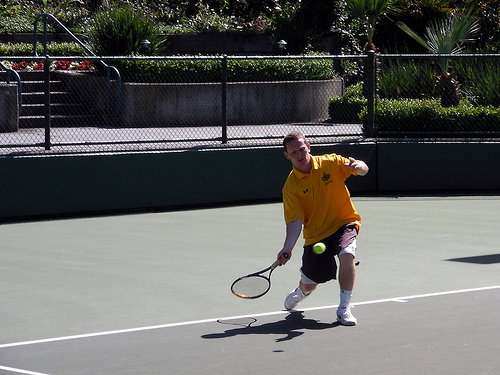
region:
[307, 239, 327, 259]
tennis ball in the air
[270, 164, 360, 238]
man wearing a yellow shirt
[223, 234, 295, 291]
man holding a tennis racket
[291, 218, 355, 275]
man wearing brown shorts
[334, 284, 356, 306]
man wearing white socks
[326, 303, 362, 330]
man wearing white shoes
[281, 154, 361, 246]
man has on a yellow shirt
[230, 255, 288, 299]
man is holding a black racket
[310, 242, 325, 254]
green tennis ball is in the air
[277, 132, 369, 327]
man is on a tennis court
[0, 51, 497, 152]
fence is black and metal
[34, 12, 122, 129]
railing is black and metal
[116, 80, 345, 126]
wall is concrete and gray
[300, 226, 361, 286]
mans shorts are black and white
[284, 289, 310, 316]
mans shoe is black and white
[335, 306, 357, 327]
mans shoe is black and white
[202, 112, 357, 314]
the man is playing tennis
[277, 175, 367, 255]
the shirt is yellow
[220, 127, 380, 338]
tennis player hitting a ball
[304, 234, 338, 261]
the ball in the air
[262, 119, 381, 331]
player with a yellow shirt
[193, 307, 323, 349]
shadow on the ground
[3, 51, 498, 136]
a fence color black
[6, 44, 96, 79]
red and white flowers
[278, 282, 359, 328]
shoes color white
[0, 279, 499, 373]
white lines on the floor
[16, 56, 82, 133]
the stair of concrete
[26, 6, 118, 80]
a black rail of the stairs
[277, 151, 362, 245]
yellow shirt of the amateur player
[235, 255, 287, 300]
racquet of the amateur player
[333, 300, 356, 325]
shoe of the amateur player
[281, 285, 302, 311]
shoe of the amateur player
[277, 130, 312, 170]
head of the amateur player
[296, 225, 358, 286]
maroon shorts of the amateur player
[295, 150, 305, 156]
nose of the amateur player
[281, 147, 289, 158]
ear of the amateur player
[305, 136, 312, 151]
ear of the amateur player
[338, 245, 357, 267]
knee of the amateur player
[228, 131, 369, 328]
man about to hit a ball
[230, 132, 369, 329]
tennis player hitting the ball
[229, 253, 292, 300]
tennis racket in a hand